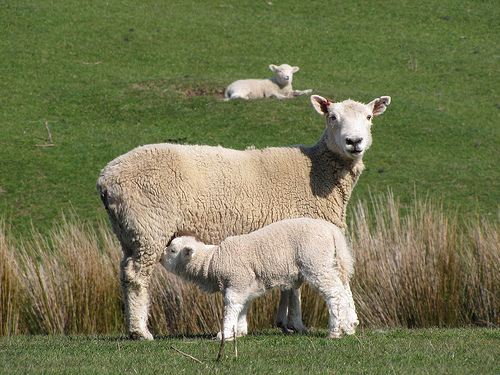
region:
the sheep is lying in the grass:
[200, 48, 453, 210]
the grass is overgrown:
[387, 167, 488, 316]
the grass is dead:
[380, 220, 499, 346]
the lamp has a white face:
[273, 100, 475, 220]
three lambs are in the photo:
[172, 7, 416, 362]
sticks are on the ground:
[185, 325, 247, 373]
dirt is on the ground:
[126, 35, 272, 167]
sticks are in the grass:
[10, 111, 118, 218]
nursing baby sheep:
[152, 220, 214, 292]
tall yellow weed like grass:
[391, 211, 481, 328]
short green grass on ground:
[333, 348, 409, 369]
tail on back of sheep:
[327, 219, 360, 283]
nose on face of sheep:
[334, 131, 376, 151]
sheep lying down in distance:
[196, 66, 369, 110]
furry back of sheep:
[173, 148, 278, 189]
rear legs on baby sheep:
[315, 255, 379, 342]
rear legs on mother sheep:
[91, 200, 170, 347]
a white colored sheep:
[216, 60, 314, 105]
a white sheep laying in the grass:
[215, 61, 317, 103]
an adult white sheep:
[98, 93, 391, 345]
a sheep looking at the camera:
[95, 93, 391, 339]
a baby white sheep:
[160, 217, 355, 342]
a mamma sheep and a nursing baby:
[93, 90, 389, 340]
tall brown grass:
[1, 195, 498, 332]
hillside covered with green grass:
[6, 1, 498, 250]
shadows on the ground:
[81, 327, 329, 344]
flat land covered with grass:
[6, 325, 497, 374]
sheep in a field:
[109, 67, 389, 317]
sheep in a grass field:
[92, 95, 354, 367]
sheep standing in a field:
[140, 47, 404, 373]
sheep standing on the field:
[89, 102, 365, 373]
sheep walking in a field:
[90, 89, 415, 366]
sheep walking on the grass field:
[114, 72, 461, 361]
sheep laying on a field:
[199, 49, 379, 149]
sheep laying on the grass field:
[189, 32, 358, 168]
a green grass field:
[64, 10, 353, 218]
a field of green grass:
[83, 25, 274, 147]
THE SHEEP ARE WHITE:
[78, 48, 398, 346]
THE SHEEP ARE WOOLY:
[76, 91, 416, 336]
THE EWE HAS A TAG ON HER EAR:
[316, 95, 326, 110]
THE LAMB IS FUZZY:
[153, 210, 358, 348]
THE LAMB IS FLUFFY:
[137, 203, 368, 348]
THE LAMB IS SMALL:
[165, 210, 375, 345]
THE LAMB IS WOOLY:
[152, 225, 359, 340]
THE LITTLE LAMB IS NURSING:
[150, 205, 368, 348]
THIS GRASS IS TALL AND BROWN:
[0, 202, 499, 329]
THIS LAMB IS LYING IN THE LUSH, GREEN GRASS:
[216, 58, 312, 108]